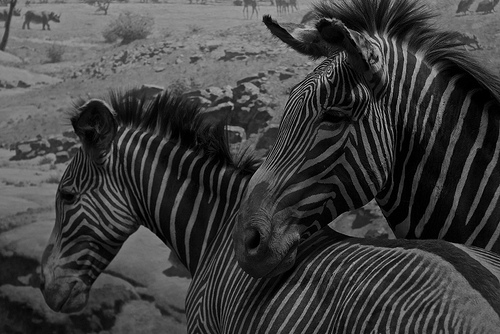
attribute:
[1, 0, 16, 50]
trunk — narrow, tree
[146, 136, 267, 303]
stripes — long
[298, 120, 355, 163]
stripe — black, white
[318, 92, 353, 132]
eye — black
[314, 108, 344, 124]
eye — round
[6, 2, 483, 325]
ground — sloped, rocky, dirty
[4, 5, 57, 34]
animal — top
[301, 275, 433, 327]
stripes — thin, light, over dark background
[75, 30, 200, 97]
rocks — pile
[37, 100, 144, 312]
animal's head — profile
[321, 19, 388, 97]
ears — animal's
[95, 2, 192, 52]
bush — small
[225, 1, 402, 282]
head — zebra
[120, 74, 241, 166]
mane — bushy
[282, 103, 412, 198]
stripes — long, thin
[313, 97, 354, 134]
eye — zebra's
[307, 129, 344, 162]
stripe — short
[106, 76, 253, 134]
hairs — black, standing up